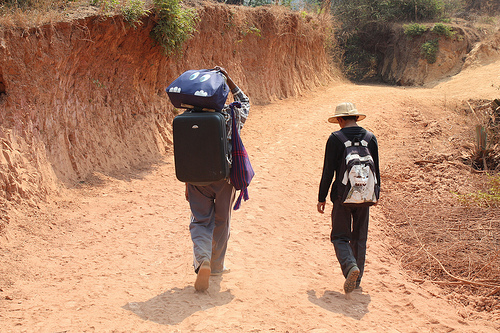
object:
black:
[331, 129, 380, 207]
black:
[171, 109, 232, 184]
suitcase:
[172, 111, 229, 183]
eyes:
[199, 74, 211, 83]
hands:
[193, 89, 208, 97]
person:
[316, 101, 382, 293]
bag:
[331, 129, 382, 208]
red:
[231, 112, 250, 208]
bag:
[227, 108, 256, 211]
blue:
[227, 101, 256, 211]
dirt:
[0, 85, 500, 333]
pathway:
[0, 83, 419, 333]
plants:
[353, 24, 369, 35]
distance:
[195, 0, 500, 86]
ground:
[0, 62, 500, 333]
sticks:
[460, 255, 463, 257]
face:
[181, 71, 215, 89]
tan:
[328, 102, 367, 124]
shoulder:
[224, 102, 251, 128]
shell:
[172, 116, 227, 183]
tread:
[194, 291, 219, 332]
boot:
[193, 260, 211, 293]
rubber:
[193, 265, 211, 292]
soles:
[342, 267, 361, 293]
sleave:
[228, 87, 251, 128]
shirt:
[184, 88, 254, 140]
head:
[190, 72, 227, 111]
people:
[168, 64, 255, 293]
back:
[171, 107, 239, 186]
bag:
[164, 67, 231, 115]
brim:
[327, 112, 368, 124]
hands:
[214, 66, 229, 79]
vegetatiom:
[105, 0, 463, 71]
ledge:
[0, 0, 335, 97]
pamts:
[329, 203, 369, 288]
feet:
[168, 86, 182, 93]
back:
[328, 127, 380, 208]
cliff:
[0, 0, 341, 200]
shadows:
[181, 300, 190, 309]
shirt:
[317, 125, 382, 205]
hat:
[327, 101, 366, 123]